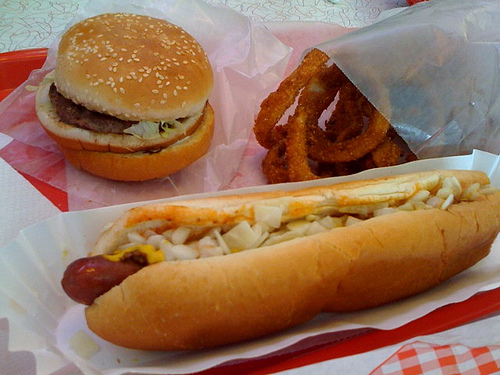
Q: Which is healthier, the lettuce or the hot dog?
A: The lettuce is healthier than the hot dog.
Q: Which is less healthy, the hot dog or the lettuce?
A: The hot dog is less healthy than the lettuce.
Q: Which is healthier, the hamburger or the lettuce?
A: The lettuce is healthier than the hamburger.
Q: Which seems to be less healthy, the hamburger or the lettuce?
A: The hamburger is less healthy than the lettuce.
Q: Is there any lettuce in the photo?
A: Yes, there is lettuce.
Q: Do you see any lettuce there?
A: Yes, there is lettuce.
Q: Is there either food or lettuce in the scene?
A: Yes, there is lettuce.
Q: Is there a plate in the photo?
A: No, there are no plates.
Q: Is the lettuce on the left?
A: Yes, the lettuce is on the left of the image.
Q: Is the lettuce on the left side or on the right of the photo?
A: The lettuce is on the left of the image.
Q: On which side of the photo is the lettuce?
A: The lettuce is on the left of the image.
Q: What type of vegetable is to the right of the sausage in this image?
A: The vegetable is lettuce.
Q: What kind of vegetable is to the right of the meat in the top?
A: The vegetable is lettuce.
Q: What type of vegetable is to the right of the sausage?
A: The vegetable is lettuce.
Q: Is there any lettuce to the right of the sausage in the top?
A: Yes, there is lettuce to the right of the sausage.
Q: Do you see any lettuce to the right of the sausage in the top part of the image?
A: Yes, there is lettuce to the right of the sausage.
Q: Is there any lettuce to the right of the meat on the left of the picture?
A: Yes, there is lettuce to the right of the sausage.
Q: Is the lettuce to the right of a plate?
A: No, the lettuce is to the right of the sausage.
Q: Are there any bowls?
A: No, there are no bowls.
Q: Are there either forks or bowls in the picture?
A: No, there are no bowls or forks.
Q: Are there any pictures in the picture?
A: No, there are no pictures.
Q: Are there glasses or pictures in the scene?
A: No, there are no pictures or glasses.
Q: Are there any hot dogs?
A: Yes, there is a hot dog.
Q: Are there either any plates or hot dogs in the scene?
A: Yes, there is a hot dog.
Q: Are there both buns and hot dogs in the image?
A: Yes, there are both a hot dog and a bun.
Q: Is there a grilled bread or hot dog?
A: Yes, there is a grilled hot dog.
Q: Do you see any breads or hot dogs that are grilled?
A: Yes, the hot dog is grilled.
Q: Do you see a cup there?
A: No, there are no cups.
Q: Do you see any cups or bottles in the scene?
A: No, there are no cups or bottles.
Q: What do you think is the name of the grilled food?
A: The food is a hot dog.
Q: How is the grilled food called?
A: The food is a hot dog.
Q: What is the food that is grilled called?
A: The food is a hot dog.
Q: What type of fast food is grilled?
A: The fast food is a hot dog.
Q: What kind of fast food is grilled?
A: The fast food is a hot dog.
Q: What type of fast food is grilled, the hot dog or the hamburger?
A: The hot dog is grilled.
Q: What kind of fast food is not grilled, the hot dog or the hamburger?
A: The hamburger is not grilled.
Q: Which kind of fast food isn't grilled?
A: The fast food is a hamburger.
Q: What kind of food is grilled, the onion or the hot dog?
A: The hot dog is grilled.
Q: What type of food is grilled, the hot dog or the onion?
A: The hot dog is grilled.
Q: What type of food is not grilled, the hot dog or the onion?
A: The onion is not grilled.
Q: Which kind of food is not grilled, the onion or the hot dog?
A: The onion is not grilled.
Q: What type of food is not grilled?
A: The food is an onion.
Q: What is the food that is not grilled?
A: The food is an onion.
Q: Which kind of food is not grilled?
A: The food is an onion.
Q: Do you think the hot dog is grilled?
A: Yes, the hot dog is grilled.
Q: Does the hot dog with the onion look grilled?
A: Yes, the hot dog is grilled.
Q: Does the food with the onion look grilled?
A: Yes, the hot dog is grilled.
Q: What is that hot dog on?
A: The hot dog is on the paper.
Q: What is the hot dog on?
A: The hot dog is on the paper.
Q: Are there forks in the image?
A: No, there are no forks.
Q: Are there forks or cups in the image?
A: No, there are no forks or cups.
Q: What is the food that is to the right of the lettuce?
A: The food is onion rings.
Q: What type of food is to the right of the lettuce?
A: The food is onion rings.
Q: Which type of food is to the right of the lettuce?
A: The food is onion rings.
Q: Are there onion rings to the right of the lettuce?
A: Yes, there are onion rings to the right of the lettuce.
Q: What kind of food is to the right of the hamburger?
A: The food is onion rings.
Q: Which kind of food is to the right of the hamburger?
A: The food is onion rings.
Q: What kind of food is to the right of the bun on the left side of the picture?
A: The food is onion rings.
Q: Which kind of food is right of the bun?
A: The food is onion rings.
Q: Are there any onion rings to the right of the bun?
A: Yes, there are onion rings to the right of the bun.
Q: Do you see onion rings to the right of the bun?
A: Yes, there are onion rings to the right of the bun.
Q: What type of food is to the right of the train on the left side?
A: The food is onion rings.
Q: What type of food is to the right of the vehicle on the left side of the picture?
A: The food is onion rings.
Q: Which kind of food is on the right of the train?
A: The food is onion rings.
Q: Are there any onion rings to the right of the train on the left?
A: Yes, there are onion rings to the right of the train.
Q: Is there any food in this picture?
A: Yes, there is food.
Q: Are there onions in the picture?
A: Yes, there are onions.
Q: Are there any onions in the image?
A: Yes, there are onions.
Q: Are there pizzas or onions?
A: Yes, there are onions.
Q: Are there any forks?
A: No, there are no forks.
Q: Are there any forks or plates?
A: No, there are no forks or plates.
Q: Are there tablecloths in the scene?
A: Yes, there is a tablecloth.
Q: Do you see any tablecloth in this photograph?
A: Yes, there is a tablecloth.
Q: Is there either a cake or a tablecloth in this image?
A: Yes, there is a tablecloth.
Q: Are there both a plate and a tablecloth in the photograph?
A: No, there is a tablecloth but no plates.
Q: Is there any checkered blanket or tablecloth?
A: Yes, there is a checkered tablecloth.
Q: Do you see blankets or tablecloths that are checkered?
A: Yes, the tablecloth is checkered.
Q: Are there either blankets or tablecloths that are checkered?
A: Yes, the tablecloth is checkered.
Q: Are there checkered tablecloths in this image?
A: Yes, there is a checkered tablecloth.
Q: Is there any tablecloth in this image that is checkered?
A: Yes, there is a tablecloth that is checkered.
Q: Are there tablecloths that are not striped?
A: Yes, there is a checkered tablecloth.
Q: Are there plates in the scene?
A: No, there are no plates.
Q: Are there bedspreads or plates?
A: No, there are no plates or bedspreads.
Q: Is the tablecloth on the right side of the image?
A: Yes, the tablecloth is on the right of the image.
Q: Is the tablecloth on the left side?
A: No, the tablecloth is on the right of the image.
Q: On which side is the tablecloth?
A: The tablecloth is on the right of the image.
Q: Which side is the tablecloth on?
A: The tablecloth is on the right of the image.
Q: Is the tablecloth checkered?
A: Yes, the tablecloth is checkered.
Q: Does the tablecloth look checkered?
A: Yes, the tablecloth is checkered.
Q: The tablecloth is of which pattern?
A: The tablecloth is checkered.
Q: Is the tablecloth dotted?
A: No, the tablecloth is checkered.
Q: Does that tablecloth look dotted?
A: No, the tablecloth is checkered.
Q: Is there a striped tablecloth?
A: No, there is a tablecloth but it is checkered.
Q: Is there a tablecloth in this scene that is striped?
A: No, there is a tablecloth but it is checkered.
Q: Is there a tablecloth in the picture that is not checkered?
A: No, there is a tablecloth but it is checkered.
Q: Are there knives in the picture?
A: No, there are no knives.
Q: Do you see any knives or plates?
A: No, there are no knives or plates.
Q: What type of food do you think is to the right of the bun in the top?
A: The food is onion rings.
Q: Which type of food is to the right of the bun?
A: The food is onion rings.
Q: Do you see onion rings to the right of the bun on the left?
A: Yes, there are onion rings to the right of the bun.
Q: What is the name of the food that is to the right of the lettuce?
A: The food is onion rings.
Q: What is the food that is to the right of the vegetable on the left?
A: The food is onion rings.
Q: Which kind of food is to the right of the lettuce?
A: The food is onion rings.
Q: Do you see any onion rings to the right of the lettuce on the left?
A: Yes, there are onion rings to the right of the lettuce.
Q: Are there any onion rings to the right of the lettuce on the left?
A: Yes, there are onion rings to the right of the lettuce.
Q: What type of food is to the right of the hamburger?
A: The food is onion rings.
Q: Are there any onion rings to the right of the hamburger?
A: Yes, there are onion rings to the right of the hamburger.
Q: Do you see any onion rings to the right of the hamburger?
A: Yes, there are onion rings to the right of the hamburger.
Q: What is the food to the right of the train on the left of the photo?
A: The food is onion rings.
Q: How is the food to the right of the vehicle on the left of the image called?
A: The food is onion rings.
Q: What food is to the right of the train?
A: The food is onion rings.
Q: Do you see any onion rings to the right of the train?
A: Yes, there are onion rings to the right of the train.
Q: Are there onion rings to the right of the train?
A: Yes, there are onion rings to the right of the train.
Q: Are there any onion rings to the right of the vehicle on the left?
A: Yes, there are onion rings to the right of the train.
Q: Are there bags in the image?
A: Yes, there is a bag.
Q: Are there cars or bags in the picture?
A: Yes, there is a bag.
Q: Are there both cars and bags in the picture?
A: No, there is a bag but no cars.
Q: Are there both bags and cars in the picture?
A: No, there is a bag but no cars.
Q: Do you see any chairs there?
A: No, there are no chairs.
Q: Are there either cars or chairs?
A: No, there are no chairs or cars.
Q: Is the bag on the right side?
A: Yes, the bag is on the right of the image.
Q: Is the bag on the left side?
A: No, the bag is on the right of the image.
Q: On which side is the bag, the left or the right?
A: The bag is on the right of the image.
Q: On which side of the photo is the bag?
A: The bag is on the right of the image.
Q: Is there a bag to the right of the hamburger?
A: Yes, there is a bag to the right of the hamburger.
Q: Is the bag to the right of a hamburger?
A: Yes, the bag is to the right of a hamburger.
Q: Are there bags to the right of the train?
A: Yes, there is a bag to the right of the train.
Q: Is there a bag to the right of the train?
A: Yes, there is a bag to the right of the train.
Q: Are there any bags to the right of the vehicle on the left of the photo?
A: Yes, there is a bag to the right of the train.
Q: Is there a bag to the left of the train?
A: No, the bag is to the right of the train.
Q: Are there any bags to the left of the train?
A: No, the bag is to the right of the train.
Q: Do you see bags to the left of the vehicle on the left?
A: No, the bag is to the right of the train.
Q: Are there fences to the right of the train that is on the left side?
A: No, there is a bag to the right of the train.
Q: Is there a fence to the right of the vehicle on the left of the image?
A: No, there is a bag to the right of the train.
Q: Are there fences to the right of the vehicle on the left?
A: No, there is a bag to the right of the train.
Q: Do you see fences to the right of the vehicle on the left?
A: No, there is a bag to the right of the train.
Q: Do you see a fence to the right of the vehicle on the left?
A: No, there is a bag to the right of the train.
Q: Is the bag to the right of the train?
A: Yes, the bag is to the right of the train.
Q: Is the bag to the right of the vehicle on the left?
A: Yes, the bag is to the right of the train.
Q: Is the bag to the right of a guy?
A: No, the bag is to the right of the train.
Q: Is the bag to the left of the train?
A: No, the bag is to the right of the train.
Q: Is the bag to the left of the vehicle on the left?
A: No, the bag is to the right of the train.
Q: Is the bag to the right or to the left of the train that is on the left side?
A: The bag is to the right of the train.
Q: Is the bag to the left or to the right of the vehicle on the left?
A: The bag is to the right of the train.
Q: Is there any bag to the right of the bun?
A: Yes, there is a bag to the right of the bun.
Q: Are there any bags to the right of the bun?
A: Yes, there is a bag to the right of the bun.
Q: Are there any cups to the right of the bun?
A: No, there is a bag to the right of the bun.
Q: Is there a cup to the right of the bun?
A: No, there is a bag to the right of the bun.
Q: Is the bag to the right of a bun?
A: Yes, the bag is to the right of a bun.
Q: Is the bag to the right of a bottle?
A: No, the bag is to the right of a bun.